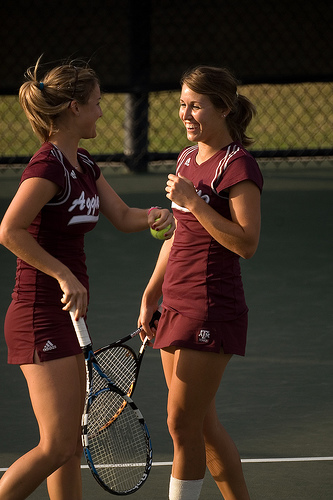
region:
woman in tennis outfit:
[141, 65, 304, 449]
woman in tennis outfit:
[0, 88, 135, 499]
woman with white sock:
[167, 340, 216, 497]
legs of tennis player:
[8, 337, 95, 498]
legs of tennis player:
[153, 340, 236, 495]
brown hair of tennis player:
[9, 54, 116, 151]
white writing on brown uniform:
[33, 148, 115, 244]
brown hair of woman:
[166, 61, 253, 159]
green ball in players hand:
[149, 201, 177, 255]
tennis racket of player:
[48, 271, 186, 478]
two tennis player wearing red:
[33, 64, 251, 480]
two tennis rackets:
[58, 286, 185, 494]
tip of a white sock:
[161, 466, 227, 498]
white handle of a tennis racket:
[59, 289, 107, 367]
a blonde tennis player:
[25, 53, 112, 154]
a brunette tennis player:
[173, 55, 260, 163]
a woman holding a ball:
[122, 183, 172, 250]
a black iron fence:
[129, 3, 326, 61]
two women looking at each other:
[16, 61, 279, 211]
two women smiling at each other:
[9, 56, 273, 181]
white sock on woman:
[163, 455, 210, 499]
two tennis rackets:
[78, 317, 161, 471]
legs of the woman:
[148, 354, 247, 473]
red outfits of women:
[4, 137, 282, 373]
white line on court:
[271, 432, 317, 490]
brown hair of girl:
[20, 41, 119, 145]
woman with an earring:
[166, 49, 281, 156]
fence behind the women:
[100, 16, 195, 104]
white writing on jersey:
[61, 191, 107, 230]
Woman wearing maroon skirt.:
[177, 309, 248, 370]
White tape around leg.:
[170, 463, 196, 495]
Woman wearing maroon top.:
[162, 273, 244, 310]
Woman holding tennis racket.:
[112, 331, 188, 366]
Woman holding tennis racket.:
[64, 273, 117, 423]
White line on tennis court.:
[241, 415, 282, 484]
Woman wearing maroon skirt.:
[21, 320, 85, 368]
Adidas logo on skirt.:
[40, 330, 77, 381]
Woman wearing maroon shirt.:
[45, 240, 76, 272]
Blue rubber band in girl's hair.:
[18, 66, 55, 111]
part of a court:
[273, 381, 297, 409]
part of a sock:
[175, 483, 188, 495]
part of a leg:
[172, 437, 191, 482]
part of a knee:
[159, 411, 193, 444]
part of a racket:
[103, 434, 133, 464]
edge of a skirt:
[183, 337, 212, 366]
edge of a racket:
[73, 448, 99, 475]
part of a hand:
[132, 291, 159, 330]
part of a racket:
[93, 400, 121, 431]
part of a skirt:
[34, 330, 54, 342]